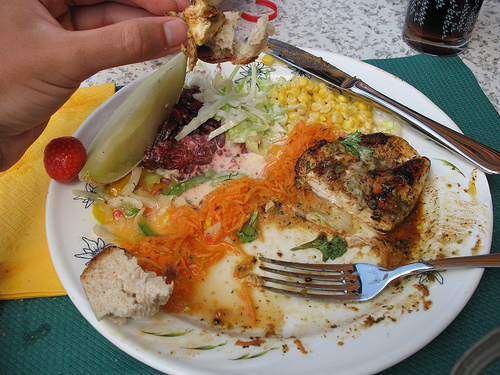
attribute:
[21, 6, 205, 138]
hand — holding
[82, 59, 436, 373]
food — eaten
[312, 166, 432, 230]
chicken — piece, breast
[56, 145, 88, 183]
strawberry — red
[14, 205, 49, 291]
napkin — yellow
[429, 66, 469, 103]
mat — green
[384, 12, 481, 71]
glass — clear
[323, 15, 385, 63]
table — white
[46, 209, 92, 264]
plate — white, large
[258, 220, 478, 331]
fork — silver, metal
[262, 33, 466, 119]
knife — silver, metal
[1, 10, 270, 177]
person — holding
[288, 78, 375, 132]
corn — cooked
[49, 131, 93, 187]
berry — round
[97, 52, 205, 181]
melon — green